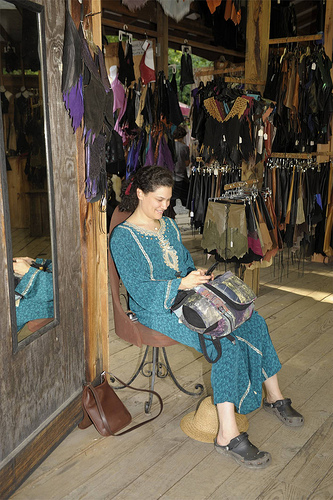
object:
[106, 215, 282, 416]
dress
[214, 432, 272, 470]
clog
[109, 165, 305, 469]
woman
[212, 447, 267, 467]
dirt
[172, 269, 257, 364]
handbag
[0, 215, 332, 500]
floor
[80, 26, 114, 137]
vest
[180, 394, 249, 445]
hat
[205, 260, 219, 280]
phone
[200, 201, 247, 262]
skirt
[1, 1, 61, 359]
mirror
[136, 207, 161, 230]
necklace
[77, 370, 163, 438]
purse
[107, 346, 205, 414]
bottom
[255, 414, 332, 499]
plank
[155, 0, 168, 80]
post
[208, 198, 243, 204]
hanger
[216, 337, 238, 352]
lap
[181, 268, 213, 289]
hand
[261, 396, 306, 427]
crocket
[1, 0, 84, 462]
wall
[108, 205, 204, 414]
chair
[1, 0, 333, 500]
store